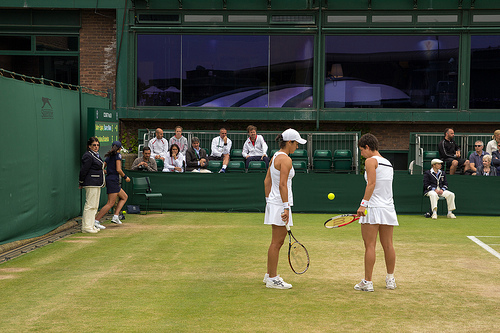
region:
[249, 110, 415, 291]
two ladies playing tennis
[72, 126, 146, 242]
two ladies standing in the sideline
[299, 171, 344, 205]
a tennis ball in the air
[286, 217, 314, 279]
tennis raquet in the ladies hand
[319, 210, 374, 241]
wilson tennis raquet in the ladies left hand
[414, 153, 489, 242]
man with white cap sitting in the sideline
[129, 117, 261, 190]
people watching in the stands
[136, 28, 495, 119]
windows behind the bleachers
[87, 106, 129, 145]
score board on the wall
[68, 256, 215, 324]
green grass on the ground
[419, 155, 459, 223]
line judge sitting in a chair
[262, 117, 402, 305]
two woman in tennis outfits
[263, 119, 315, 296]
woman holding a tennis racket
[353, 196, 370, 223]
sweatband on a wrist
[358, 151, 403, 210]
white shirt with black stripe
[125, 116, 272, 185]
specatators in sitting in gallery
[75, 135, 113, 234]
person in dark jacket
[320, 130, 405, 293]
woman bouncing tennis ball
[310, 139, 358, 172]
two green folding chairs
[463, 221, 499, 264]
boundry lines on grass tennis court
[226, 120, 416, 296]
Two women in the foreground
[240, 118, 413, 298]
Women are playing tennis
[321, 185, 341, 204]
A tennis ball in the mid air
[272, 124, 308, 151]
Woman is wearing a white cap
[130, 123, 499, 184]
People are in the background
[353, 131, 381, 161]
Woman has short hair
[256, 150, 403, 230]
Women are wearing sport dresses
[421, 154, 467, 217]
A person is sitting down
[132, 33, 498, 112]
Tinted windows in the background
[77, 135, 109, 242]
Woman is wearing white pants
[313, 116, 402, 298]
woman bouncing tennis ball on racket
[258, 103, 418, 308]
women standing on tennis court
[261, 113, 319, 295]
woman wearing white baseball cap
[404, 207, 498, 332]
grass tennis court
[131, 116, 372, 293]
seats on tennis court sidelines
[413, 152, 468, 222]
tennis official wearing blue blazer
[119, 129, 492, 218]
green plastic screen in front of seating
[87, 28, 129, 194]
green scoreboard by wall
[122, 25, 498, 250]
glass wall overlooking tennis court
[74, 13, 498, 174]
building made of brick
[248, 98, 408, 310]
two players are standing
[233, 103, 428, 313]
they are wearing a white uniform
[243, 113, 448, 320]
the are holding rackets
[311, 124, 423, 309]
the lady is playing with a ball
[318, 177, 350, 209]
the ball is green in colour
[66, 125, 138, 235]
people are standing on the side of the field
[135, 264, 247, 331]
the grass is green in colour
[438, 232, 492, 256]
the grass has stripes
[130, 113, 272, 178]
the spectators are seated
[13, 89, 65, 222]
the wall is green